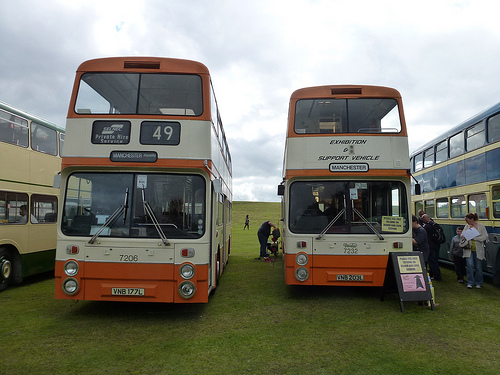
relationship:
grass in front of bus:
[3, 292, 498, 373] [281, 75, 420, 292]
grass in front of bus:
[3, 292, 498, 373] [48, 52, 230, 316]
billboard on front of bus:
[380, 251, 435, 313] [266, 73, 417, 313]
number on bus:
[153, 126, 173, 141] [48, 52, 230, 316]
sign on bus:
[108, 150, 160, 163] [48, 52, 230, 316]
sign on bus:
[328, 160, 367, 171] [281, 75, 420, 292]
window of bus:
[61, 170, 204, 240] [48, 52, 230, 316]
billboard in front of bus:
[380, 251, 435, 313] [297, 75, 388, 295]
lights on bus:
[61, 257, 78, 276] [48, 52, 230, 316]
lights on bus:
[60, 274, 77, 297] [48, 52, 230, 316]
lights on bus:
[178, 262, 195, 278] [48, 52, 230, 316]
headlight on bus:
[295, 253, 309, 266] [281, 75, 420, 292]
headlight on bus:
[295, 266, 309, 281] [281, 75, 420, 292]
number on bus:
[151, 119, 175, 143] [48, 52, 230, 316]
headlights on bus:
[64, 257, 80, 296] [48, 52, 230, 316]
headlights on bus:
[177, 252, 195, 297] [281, 75, 420, 292]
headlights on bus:
[291, 246, 309, 277] [0, 110, 59, 290]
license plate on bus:
[336, 270, 369, 280] [274, 75, 434, 306]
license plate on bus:
[109, 285, 149, 296] [30, 39, 252, 323]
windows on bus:
[0, 190, 57, 225] [0, 102, 68, 289]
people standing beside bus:
[410, 205, 491, 292] [281, 75, 420, 292]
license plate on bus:
[336, 274, 364, 281] [284, 67, 454, 325]